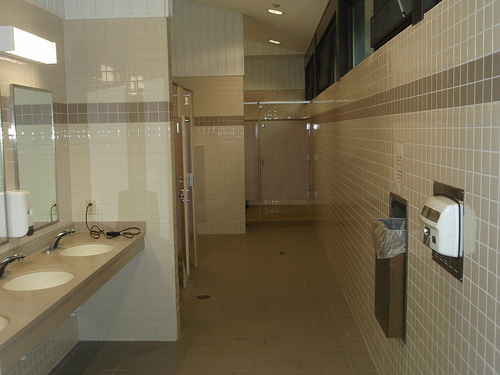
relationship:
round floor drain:
[188, 233, 298, 375] [193, 291, 212, 300]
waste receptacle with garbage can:
[315, 208, 413, 343] [369, 216, 407, 340]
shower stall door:
[246, 85, 318, 214] [257, 117, 313, 202]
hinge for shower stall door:
[301, 186, 315, 200] [254, 100, 313, 220]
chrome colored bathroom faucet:
[51, 185, 98, 268] [40, 225, 78, 256]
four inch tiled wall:
[224, 91, 301, 190] [314, 114, 394, 294]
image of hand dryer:
[463, 204, 480, 258] [416, 188, 463, 263]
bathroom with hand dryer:
[89, 45, 423, 322] [416, 192, 461, 260]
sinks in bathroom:
[6, 233, 118, 294] [1, 1, 496, 372]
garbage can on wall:
[369, 216, 407, 340] [305, 38, 492, 373]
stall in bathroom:
[243, 116, 318, 226] [1, 1, 496, 372]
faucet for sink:
[43, 224, 81, 253] [63, 237, 122, 269]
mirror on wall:
[8, 85, 63, 232] [1, 1, 71, 373]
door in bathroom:
[175, 120, 189, 287] [1, 1, 496, 372]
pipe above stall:
[243, 96, 310, 106] [243, 116, 318, 226]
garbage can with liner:
[369, 216, 407, 340] [373, 215, 405, 253]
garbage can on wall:
[369, 216, 407, 340] [360, 154, 427, 374]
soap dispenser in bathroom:
[4, 181, 36, 239] [1, 1, 496, 372]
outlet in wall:
[81, 194, 99, 219] [55, 0, 186, 347]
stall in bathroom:
[227, 74, 332, 231] [0, 0, 499, 375]